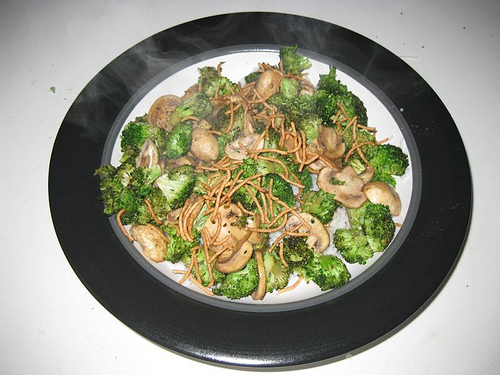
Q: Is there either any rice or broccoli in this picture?
A: Yes, there is broccoli.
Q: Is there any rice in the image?
A: No, there is no rice.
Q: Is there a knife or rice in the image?
A: No, there are no rice or knives.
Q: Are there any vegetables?
A: Yes, there are vegetables.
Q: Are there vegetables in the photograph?
A: Yes, there are vegetables.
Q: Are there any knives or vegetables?
A: Yes, there are vegetables.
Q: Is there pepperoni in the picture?
A: No, there is no pepperoni.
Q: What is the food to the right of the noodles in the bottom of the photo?
A: The food is a mushroom.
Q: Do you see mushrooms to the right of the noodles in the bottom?
A: Yes, there is a mushroom to the right of the noodles.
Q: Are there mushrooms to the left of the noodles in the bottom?
A: No, the mushroom is to the right of the noodles.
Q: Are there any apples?
A: No, there are no apples.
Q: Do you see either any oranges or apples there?
A: No, there are no apples or oranges.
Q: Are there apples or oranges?
A: No, there are no apples or oranges.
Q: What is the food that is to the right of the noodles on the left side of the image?
A: The food is a mushroom.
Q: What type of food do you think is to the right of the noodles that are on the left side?
A: The food is a mushroom.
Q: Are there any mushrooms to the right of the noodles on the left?
A: Yes, there is a mushroom to the right of the noodles.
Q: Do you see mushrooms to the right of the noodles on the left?
A: Yes, there is a mushroom to the right of the noodles.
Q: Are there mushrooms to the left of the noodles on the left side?
A: No, the mushroom is to the right of the noodles.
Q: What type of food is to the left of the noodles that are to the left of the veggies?
A: The food is a mushroom.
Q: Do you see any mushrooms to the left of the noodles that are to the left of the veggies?
A: Yes, there is a mushroom to the left of the noodles.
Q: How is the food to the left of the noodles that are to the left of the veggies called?
A: The food is a mushroom.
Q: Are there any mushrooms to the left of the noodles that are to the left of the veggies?
A: Yes, there is a mushroom to the left of the noodles.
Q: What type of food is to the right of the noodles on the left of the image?
A: The food is a mushroom.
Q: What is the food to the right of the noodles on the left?
A: The food is a mushroom.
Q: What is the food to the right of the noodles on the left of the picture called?
A: The food is a mushroom.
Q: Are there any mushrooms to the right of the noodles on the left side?
A: Yes, there is a mushroom to the right of the noodles.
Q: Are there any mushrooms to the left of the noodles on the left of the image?
A: No, the mushroom is to the right of the noodles.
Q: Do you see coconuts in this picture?
A: No, there are no coconuts.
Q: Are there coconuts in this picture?
A: No, there are no coconuts.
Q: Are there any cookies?
A: No, there are no cookies.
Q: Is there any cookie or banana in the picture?
A: No, there are no cookies or bananas.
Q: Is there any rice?
A: No, there is no rice.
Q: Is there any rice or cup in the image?
A: No, there are no rice or cups.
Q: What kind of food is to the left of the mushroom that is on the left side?
A: The food is noodles.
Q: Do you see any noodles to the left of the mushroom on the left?
A: Yes, there are noodles to the left of the mushroom.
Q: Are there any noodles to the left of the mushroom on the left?
A: Yes, there are noodles to the left of the mushroom.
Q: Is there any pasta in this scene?
A: No, there is no pasta.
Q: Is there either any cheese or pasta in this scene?
A: No, there are no pasta or cheese.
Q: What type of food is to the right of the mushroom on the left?
A: The food is noodles.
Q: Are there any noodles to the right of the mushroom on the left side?
A: Yes, there are noodles to the right of the mushroom.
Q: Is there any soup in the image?
A: No, there is no soup.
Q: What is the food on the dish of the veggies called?
A: The food is a mushroom.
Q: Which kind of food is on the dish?
A: The food is a mushroom.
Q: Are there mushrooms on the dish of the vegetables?
A: Yes, there is a mushroom on the dish.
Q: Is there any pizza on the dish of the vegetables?
A: No, there is a mushroom on the dish.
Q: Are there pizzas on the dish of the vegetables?
A: No, there is a mushroom on the dish.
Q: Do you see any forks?
A: No, there are no forks.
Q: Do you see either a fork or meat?
A: No, there are no forks or meat.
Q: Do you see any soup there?
A: No, there is no soup.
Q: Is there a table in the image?
A: Yes, there is a table.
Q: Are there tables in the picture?
A: Yes, there is a table.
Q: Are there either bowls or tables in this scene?
A: Yes, there is a table.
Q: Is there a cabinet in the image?
A: No, there are no cabinets.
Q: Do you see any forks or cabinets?
A: No, there are no cabinets or forks.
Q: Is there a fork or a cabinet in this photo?
A: No, there are no cabinets or forks.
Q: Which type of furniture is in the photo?
A: The furniture is a table.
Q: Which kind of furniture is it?
A: The piece of furniture is a table.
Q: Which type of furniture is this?
A: This is a table.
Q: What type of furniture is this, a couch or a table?
A: This is a table.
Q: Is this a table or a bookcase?
A: This is a table.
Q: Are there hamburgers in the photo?
A: No, there are no hamburgers.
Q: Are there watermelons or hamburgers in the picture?
A: No, there are no hamburgers or watermelons.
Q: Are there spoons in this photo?
A: No, there are no spoons.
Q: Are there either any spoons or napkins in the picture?
A: No, there are no spoons or napkins.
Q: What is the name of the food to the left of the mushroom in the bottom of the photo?
A: The food is noodles.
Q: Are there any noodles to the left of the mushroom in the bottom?
A: Yes, there are noodles to the left of the mushroom.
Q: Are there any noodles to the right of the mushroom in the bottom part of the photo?
A: No, the noodles are to the left of the mushroom.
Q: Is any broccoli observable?
A: Yes, there is broccoli.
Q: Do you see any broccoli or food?
A: Yes, there is broccoli.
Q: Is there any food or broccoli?
A: Yes, there is broccoli.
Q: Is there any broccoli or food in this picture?
A: Yes, there is broccoli.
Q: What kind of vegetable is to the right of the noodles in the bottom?
A: The vegetable is broccoli.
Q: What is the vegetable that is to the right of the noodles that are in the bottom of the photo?
A: The vegetable is broccoli.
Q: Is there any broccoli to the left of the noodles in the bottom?
A: No, the broccoli is to the right of the noodles.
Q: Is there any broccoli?
A: Yes, there is broccoli.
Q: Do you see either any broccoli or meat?
A: Yes, there is broccoli.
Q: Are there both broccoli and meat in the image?
A: No, there is broccoli but no meat.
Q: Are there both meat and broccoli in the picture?
A: No, there is broccoli but no meat.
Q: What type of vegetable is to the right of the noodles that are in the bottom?
A: The vegetable is broccoli.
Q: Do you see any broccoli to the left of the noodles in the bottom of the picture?
A: No, the broccoli is to the right of the noodles.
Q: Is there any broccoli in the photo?
A: Yes, there is broccoli.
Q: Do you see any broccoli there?
A: Yes, there is broccoli.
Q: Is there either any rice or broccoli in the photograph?
A: Yes, there is broccoli.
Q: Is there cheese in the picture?
A: No, there is no cheese.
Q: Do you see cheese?
A: No, there is no cheese.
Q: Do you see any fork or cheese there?
A: No, there are no cheese or forks.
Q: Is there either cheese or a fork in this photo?
A: No, there are no cheese or forks.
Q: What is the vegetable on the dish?
A: The vegetable is broccoli.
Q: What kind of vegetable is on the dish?
A: The vegetable is broccoli.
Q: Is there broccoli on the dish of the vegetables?
A: Yes, there is broccoli on the dish.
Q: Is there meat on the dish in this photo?
A: No, there is broccoli on the dish.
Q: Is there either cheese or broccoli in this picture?
A: Yes, there is broccoli.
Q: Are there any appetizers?
A: No, there are no appetizers.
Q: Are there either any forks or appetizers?
A: No, there are no appetizers or forks.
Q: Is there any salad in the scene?
A: No, there is no salad.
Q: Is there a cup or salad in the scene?
A: No, there are no salad or cups.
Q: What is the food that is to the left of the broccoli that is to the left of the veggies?
A: The food is noodles.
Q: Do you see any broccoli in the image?
A: Yes, there is broccoli.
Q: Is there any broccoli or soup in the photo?
A: Yes, there is broccoli.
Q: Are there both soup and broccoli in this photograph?
A: No, there is broccoli but no soup.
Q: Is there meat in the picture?
A: No, there is no meat.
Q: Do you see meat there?
A: No, there is no meat.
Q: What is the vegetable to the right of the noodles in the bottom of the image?
A: The vegetable is broccoli.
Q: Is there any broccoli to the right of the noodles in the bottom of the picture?
A: Yes, there is broccoli to the right of the noodles.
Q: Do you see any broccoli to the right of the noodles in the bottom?
A: Yes, there is broccoli to the right of the noodles.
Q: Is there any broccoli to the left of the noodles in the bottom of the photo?
A: No, the broccoli is to the right of the noodles.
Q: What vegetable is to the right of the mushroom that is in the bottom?
A: The vegetable is broccoli.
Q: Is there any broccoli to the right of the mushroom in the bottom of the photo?
A: Yes, there is broccoli to the right of the mushroom.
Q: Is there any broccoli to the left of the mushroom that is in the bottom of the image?
A: No, the broccoli is to the right of the mushroom.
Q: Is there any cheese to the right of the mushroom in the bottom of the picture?
A: No, there is broccoli to the right of the mushroom.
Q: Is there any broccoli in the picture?
A: Yes, there is broccoli.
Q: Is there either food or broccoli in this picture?
A: Yes, there is broccoli.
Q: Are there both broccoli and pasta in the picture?
A: No, there is broccoli but no pasta.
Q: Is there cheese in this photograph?
A: No, there is no cheese.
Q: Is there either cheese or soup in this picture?
A: No, there are no cheese or soup.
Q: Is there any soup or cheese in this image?
A: No, there are no cheese or soup.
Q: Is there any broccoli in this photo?
A: Yes, there is broccoli.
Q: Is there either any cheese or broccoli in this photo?
A: Yes, there is broccoli.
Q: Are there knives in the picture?
A: No, there are no knives.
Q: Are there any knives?
A: No, there are no knives.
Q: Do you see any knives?
A: No, there are no knives.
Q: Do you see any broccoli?
A: Yes, there is broccoli.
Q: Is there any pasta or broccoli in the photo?
A: Yes, there is broccoli.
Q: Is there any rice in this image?
A: No, there is no rice.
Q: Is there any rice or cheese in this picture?
A: No, there are no rice or cheese.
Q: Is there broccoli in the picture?
A: Yes, there is broccoli.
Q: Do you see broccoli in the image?
A: Yes, there is broccoli.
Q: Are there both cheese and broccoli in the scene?
A: No, there is broccoli but no cheese.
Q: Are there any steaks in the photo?
A: No, there are no steaks.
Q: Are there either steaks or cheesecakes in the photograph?
A: No, there are no steaks or cheesecakes.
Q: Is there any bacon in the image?
A: No, there is no bacon.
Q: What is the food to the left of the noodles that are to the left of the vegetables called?
A: The food is a mushroom.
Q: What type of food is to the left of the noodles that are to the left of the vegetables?
A: The food is a mushroom.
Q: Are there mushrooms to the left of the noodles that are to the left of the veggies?
A: Yes, there is a mushroom to the left of the noodles.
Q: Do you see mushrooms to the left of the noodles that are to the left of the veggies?
A: Yes, there is a mushroom to the left of the noodles.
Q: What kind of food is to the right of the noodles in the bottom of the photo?
A: The food is a mushroom.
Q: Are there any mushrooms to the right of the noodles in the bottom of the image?
A: Yes, there is a mushroom to the right of the noodles.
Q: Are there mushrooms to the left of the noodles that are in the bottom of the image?
A: No, the mushroom is to the right of the noodles.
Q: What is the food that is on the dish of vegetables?
A: The food is a mushroom.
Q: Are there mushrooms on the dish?
A: Yes, there is a mushroom on the dish.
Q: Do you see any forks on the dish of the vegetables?
A: No, there is a mushroom on the dish.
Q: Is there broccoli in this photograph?
A: Yes, there is broccoli.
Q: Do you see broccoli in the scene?
A: Yes, there is broccoli.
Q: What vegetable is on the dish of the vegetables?
A: The vegetable is broccoli.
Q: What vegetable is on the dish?
A: The vegetable is broccoli.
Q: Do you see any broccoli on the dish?
A: Yes, there is broccoli on the dish.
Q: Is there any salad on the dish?
A: No, there is broccoli on the dish.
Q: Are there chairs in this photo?
A: No, there are no chairs.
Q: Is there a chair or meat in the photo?
A: No, there are no chairs or meat.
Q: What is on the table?
A: The dish is on the table.